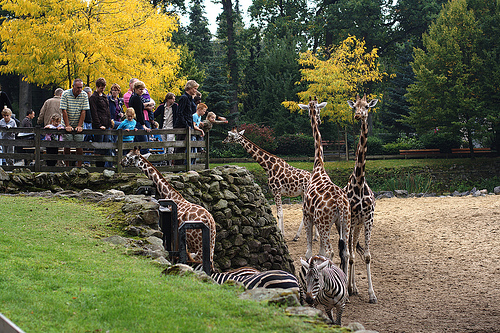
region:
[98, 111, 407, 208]
giraffes are at the zoo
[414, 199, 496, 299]
dirt is on the ground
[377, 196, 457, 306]
sticks are on the ground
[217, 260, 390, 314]
the giraffes are lying down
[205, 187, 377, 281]
a wall made of stones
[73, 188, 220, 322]
a wall made of bricks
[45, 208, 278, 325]
grass is next to the brick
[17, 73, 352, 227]
people are watching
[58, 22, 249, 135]
the branches have yellow leaves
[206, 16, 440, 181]
the trees are lush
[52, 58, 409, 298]
people looking at giraffes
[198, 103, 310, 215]
girl reaching for giraffe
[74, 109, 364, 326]
zebras standing near giraffe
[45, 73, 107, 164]
man leaning on rail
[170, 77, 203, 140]
man wearing black shirt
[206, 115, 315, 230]
giraffe leaning head forward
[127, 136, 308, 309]
stack rocks next to giraffe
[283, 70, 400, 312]
two giraffes facing opposite directions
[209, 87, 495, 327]
giraffes standing on dirt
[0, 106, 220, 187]
brown rail and fence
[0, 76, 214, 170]
the group of people looking at the animals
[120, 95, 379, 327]
the animals in the enclosure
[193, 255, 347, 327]
the group of zebras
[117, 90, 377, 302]
the group of giraffes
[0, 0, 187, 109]
the yellow tree next to the people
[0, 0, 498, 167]
the trees outside of the animal enclosure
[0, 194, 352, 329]
the green grass near the animal enclosure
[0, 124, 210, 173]
the wooden railing the people are leaning on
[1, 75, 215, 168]
the people leaning on the railing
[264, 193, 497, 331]
the dirt in the animal enclosure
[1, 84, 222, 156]
a group of people looking at the animals in the zoo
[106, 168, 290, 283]
a wall made of stone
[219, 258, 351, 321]
some zebras standing together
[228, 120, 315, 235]
a giraffe looking at some people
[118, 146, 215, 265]
the other giraffe looking at the people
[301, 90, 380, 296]
the giraffes hanging together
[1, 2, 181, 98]
a tree with many yellow leaves on it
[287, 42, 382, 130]
another tree with many yellow leaves on it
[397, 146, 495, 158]
some benches sitting next to the trees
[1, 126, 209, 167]
a wooden fence that is surrounding the people